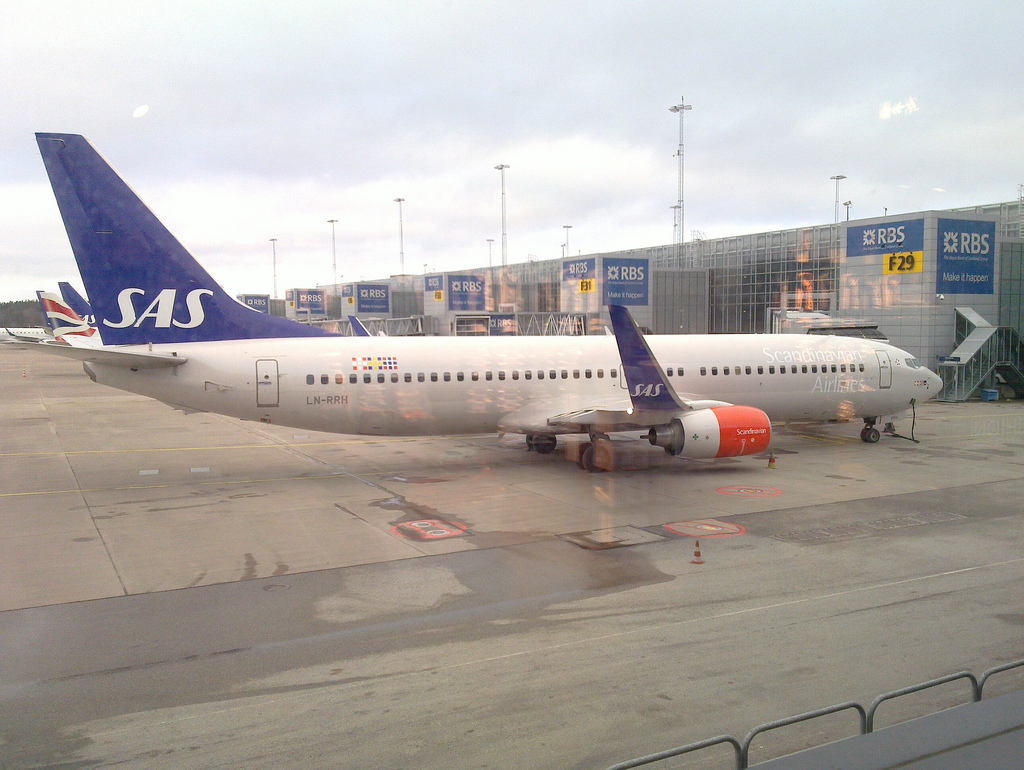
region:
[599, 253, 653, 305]
Blue and white sign is on the building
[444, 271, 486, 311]
Blue and white sign is on the building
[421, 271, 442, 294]
Blue and white sign is on the building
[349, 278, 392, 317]
Blue and white sign is on the building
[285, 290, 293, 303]
Blue and white sign is on the building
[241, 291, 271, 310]
Blue and white sign is on the building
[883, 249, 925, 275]
Yellow and black sign is on the building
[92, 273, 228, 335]
SAS on the tail of plane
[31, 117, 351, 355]
Plane tail is blue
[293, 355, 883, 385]
Passenger window on plane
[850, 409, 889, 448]
Front landing gear on plane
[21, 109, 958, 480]
Passenger jet is an SAS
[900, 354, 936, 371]
Cockpit windows on plane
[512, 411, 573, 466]
Back landing gear on plane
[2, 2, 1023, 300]
Sky is grey and cloudy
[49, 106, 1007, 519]
Plane on the runway.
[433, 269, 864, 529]
Engine on the plane.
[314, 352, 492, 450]
Windows on the plane.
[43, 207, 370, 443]
Logo on the plane.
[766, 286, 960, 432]
Door on the plane.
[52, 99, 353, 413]
Blue tail on the plane.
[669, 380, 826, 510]
Red part of the engine.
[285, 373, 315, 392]
window on the plane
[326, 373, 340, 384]
window on the plane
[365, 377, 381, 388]
window on the plane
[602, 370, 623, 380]
window on the plane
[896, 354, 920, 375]
window on the plane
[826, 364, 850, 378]
window on the plane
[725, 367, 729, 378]
window on the plane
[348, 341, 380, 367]
a window on the plane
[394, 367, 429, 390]
a window on the plane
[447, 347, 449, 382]
a window on the plane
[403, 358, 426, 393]
a window on the plane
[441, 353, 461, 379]
a window on the plane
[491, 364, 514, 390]
a window on the plane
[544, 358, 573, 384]
a window on the plane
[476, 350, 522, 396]
a window on the plane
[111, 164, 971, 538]
blue and white plane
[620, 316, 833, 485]
orange and white engine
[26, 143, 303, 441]
blue and white tail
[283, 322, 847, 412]
row of windows on plane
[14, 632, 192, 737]
tarmac is dark tan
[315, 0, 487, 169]
grey and white sky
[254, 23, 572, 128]
thick clouds in sky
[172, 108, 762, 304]
tall poles behind plane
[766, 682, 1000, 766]
grey rail on walkway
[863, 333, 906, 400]
white door on plane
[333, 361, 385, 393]
a window on the plane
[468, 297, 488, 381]
a window on the plane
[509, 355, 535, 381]
a window on the plane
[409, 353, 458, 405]
a window on the plane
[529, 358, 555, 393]
a window on the plane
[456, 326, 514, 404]
a window on the plane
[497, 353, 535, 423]
a window on the plane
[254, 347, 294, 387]
a window on the plane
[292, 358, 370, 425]
a window on the plane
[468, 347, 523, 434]
a window on the plane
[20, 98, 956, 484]
white plane on ground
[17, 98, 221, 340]
blue tail of plane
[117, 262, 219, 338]
white logo on blue tail